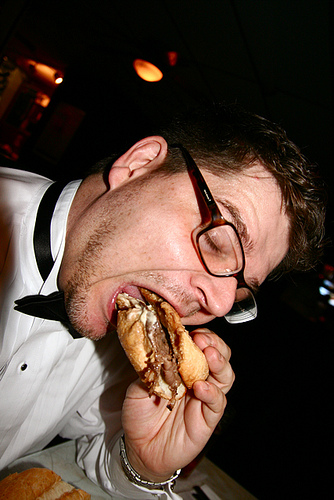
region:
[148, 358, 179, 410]
meat is hanging out of sandwich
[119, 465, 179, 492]
silver band on wrist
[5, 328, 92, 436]
man wearing a white shirt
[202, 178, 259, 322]
man is wearing glasses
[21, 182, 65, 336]
man is wearing a necktie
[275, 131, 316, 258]
man has brown hair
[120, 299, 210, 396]
a sandwich with meat and sauce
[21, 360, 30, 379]
black button on shirt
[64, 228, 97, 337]
beard on his face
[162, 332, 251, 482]
hand holding a sandwich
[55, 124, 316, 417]
man biting into sandwich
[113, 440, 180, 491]
silver band of watch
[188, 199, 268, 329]
glasses on man's face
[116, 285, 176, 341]
sandwich in man's mouth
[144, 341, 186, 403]
meat hanging out of sandwich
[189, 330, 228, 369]
fingers on sandwich bread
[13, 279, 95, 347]
black bow tie on man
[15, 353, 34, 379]
black button white shirt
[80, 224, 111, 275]
hair on man's face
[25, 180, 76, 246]
black band around collar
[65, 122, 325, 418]
man eating a hamburger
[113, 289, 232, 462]
man holding a hamburger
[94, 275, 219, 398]
man with a hamburger in his mouth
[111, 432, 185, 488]
a silver watch bracelet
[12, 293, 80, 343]
a black bow tie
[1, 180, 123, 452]
man wearing a white button-down shirt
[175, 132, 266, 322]
man wearing glasses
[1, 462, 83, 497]
bread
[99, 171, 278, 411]
man eating a hamburger with his eyes closed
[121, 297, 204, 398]
a hamburger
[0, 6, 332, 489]
man eating a messy meat sandwich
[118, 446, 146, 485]
silver watch band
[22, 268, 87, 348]
black bow tie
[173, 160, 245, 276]
dark brown glasses frames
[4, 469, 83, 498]
crunchy sandwich bread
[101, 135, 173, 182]
a man's right ear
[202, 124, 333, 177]
a man's brown hair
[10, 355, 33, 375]
black button on a dress shirt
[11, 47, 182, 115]
orange background lights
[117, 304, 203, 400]
toasted roast beef sandwich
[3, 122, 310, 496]
a man is leaning forward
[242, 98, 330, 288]
man`s hair is reddish brown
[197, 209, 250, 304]
the man`s eyes are closed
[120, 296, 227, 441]
man is holding a sandwich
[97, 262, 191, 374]
man is eating a sandwich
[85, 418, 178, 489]
man is wearing a watch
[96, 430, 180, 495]
the watch is silver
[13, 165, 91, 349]
man is wearing a bow tie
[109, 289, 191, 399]
the sandwich has meat on it